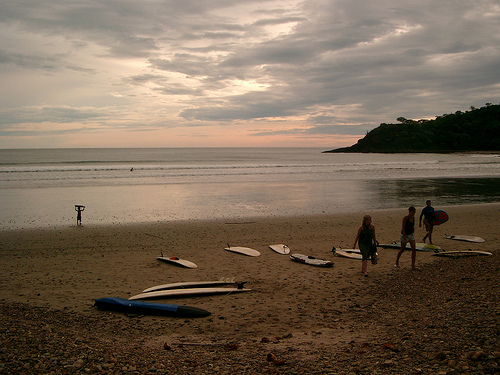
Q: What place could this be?
A: It is a beach.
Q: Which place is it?
A: It is a beach.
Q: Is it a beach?
A: Yes, it is a beach.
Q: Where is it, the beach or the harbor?
A: It is the beach.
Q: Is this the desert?
A: No, it is the beach.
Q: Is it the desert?
A: No, it is the beach.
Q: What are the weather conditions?
A: It is cloudy.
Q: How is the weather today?
A: It is cloudy.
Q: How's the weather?
A: It is cloudy.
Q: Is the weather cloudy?
A: Yes, it is cloudy.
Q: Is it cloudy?
A: Yes, it is cloudy.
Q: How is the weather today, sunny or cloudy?
A: It is cloudy.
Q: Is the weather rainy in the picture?
A: No, it is cloudy.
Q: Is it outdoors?
A: Yes, it is outdoors.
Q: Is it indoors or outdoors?
A: It is outdoors.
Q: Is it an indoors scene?
A: No, it is outdoors.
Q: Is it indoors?
A: No, it is outdoors.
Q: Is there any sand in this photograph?
A: Yes, there is sand.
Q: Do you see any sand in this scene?
A: Yes, there is sand.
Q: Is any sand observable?
A: Yes, there is sand.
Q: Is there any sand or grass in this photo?
A: Yes, there is sand.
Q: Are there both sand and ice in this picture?
A: No, there is sand but no ice.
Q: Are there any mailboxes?
A: No, there are no mailboxes.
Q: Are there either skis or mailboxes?
A: No, there are no mailboxes or skis.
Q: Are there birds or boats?
A: No, there are no boats or birds.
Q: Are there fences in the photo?
A: No, there are no fences.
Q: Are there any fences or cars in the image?
A: No, there are no fences or cars.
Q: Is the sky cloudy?
A: Yes, the sky is cloudy.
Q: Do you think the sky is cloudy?
A: Yes, the sky is cloudy.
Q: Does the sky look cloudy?
A: Yes, the sky is cloudy.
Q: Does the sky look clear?
A: No, the sky is cloudy.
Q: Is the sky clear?
A: No, the sky is cloudy.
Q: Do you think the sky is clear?
A: No, the sky is cloudy.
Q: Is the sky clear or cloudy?
A: The sky is cloudy.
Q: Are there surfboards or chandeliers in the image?
A: Yes, there is a surfboard.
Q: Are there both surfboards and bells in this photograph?
A: No, there is a surfboard but no bells.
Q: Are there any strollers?
A: No, there are no strollers.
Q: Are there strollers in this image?
A: No, there are no strollers.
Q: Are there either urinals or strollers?
A: No, there are no strollers or urinals.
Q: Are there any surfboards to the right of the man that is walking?
A: Yes, there is a surfboard to the right of the man.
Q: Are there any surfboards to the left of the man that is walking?
A: No, the surfboard is to the right of the man.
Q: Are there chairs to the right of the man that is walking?
A: No, there is a surfboard to the right of the man.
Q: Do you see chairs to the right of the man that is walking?
A: No, there is a surfboard to the right of the man.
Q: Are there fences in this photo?
A: No, there are no fences.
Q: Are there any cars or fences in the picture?
A: No, there are no fences or cars.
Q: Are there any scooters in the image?
A: No, there are no scooters.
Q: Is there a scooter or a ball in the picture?
A: No, there are no scooters or balls.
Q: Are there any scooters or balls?
A: No, there are no scooters or balls.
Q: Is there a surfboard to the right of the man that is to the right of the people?
A: Yes, there are surfboards to the right of the man.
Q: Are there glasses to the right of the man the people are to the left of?
A: No, there are surfboards to the right of the man.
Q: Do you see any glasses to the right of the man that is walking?
A: No, there are surfboards to the right of the man.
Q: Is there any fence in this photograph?
A: No, there are no fences.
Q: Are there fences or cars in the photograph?
A: No, there are no fences or cars.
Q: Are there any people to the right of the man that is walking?
A: Yes, there are people to the right of the man.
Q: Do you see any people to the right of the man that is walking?
A: Yes, there are people to the right of the man.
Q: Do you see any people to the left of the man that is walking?
A: No, the people are to the right of the man.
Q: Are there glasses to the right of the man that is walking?
A: No, there are people to the right of the man.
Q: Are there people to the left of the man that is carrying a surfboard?
A: Yes, there are people to the left of the man.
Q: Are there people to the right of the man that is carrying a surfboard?
A: No, the people are to the left of the man.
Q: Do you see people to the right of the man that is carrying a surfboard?
A: No, the people are to the left of the man.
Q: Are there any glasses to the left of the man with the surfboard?
A: No, there are people to the left of the man.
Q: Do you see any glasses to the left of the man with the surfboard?
A: No, there are people to the left of the man.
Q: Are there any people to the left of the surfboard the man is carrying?
A: Yes, there are people to the left of the surfboard.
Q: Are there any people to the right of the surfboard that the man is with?
A: No, the people are to the left of the surfboard.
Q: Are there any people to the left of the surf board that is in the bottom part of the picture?
A: Yes, there are people to the left of the surfboard.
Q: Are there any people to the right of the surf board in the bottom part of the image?
A: No, the people are to the left of the surf board.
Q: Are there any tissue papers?
A: No, there are no tissue papers.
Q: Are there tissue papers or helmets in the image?
A: No, there are no tissue papers or helmets.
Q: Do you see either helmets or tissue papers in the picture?
A: No, there are no tissue papers or helmets.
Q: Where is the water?
A: The water is on the shore.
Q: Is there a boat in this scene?
A: No, there are no boats.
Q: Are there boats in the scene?
A: No, there are no boats.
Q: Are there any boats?
A: No, there are no boats.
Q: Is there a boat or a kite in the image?
A: No, there are no boats or kites.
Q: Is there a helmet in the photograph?
A: No, there are no helmets.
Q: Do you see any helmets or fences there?
A: No, there are no helmets or fences.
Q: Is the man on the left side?
A: No, the man is on the right of the image.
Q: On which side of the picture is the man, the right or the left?
A: The man is on the right of the image.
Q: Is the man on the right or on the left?
A: The man is on the right of the image.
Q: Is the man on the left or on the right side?
A: The man is on the right of the image.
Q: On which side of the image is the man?
A: The man is on the right of the image.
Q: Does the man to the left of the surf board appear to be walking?
A: Yes, the man is walking.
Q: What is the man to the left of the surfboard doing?
A: The man is walking.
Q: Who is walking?
A: The man is walking.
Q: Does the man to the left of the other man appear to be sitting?
A: No, the man is walking.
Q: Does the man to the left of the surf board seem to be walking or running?
A: The man is walking.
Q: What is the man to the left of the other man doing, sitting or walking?
A: The man is walking.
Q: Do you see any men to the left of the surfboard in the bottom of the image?
A: Yes, there is a man to the left of the surfboard.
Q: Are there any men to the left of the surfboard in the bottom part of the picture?
A: Yes, there is a man to the left of the surfboard.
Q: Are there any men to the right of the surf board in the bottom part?
A: No, the man is to the left of the surfboard.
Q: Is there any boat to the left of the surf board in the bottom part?
A: No, there is a man to the left of the surf board.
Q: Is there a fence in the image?
A: No, there are no fences.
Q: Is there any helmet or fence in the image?
A: No, there are no fences or helmets.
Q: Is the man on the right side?
A: Yes, the man is on the right of the image.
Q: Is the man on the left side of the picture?
A: No, the man is on the right of the image.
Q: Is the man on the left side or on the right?
A: The man is on the right of the image.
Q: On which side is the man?
A: The man is on the right of the image.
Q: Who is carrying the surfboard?
A: The man is carrying the surfboard.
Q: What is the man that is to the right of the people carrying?
A: The man is carrying a surfboard.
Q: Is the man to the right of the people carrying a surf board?
A: Yes, the man is carrying a surf board.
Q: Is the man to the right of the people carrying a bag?
A: No, the man is carrying a surf board.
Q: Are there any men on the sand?
A: Yes, there is a man on the sand.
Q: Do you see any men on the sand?
A: Yes, there is a man on the sand.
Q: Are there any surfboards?
A: Yes, there is a surfboard.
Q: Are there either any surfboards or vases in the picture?
A: Yes, there is a surfboard.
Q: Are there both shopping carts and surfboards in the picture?
A: No, there is a surfboard but no shopping carts.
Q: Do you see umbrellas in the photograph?
A: No, there are no umbrellas.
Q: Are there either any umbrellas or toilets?
A: No, there are no umbrellas or toilets.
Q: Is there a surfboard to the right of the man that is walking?
A: Yes, there is a surfboard to the right of the man.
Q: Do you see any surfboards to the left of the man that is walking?
A: No, the surfboard is to the right of the man.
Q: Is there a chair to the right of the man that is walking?
A: No, there is a surfboard to the right of the man.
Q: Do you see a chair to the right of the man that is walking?
A: No, there is a surfboard to the right of the man.